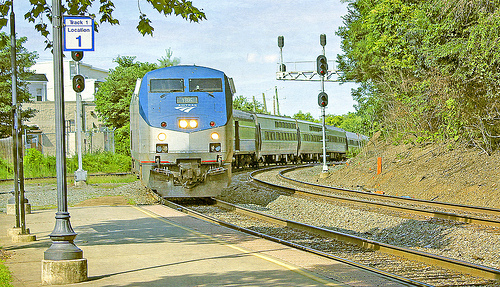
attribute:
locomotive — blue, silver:
[129, 64, 239, 194]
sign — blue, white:
[62, 17, 94, 52]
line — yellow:
[144, 207, 179, 230]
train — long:
[138, 77, 354, 176]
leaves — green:
[373, 4, 416, 39]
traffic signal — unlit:
[316, 90, 332, 109]